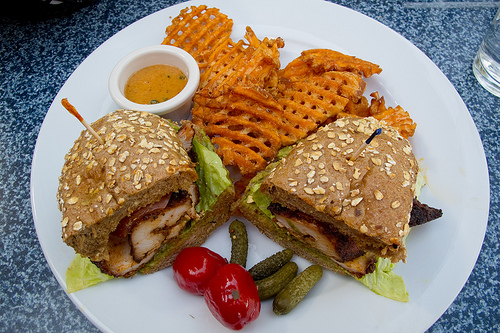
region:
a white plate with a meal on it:
[31, 0, 491, 332]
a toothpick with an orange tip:
[60, 97, 103, 147]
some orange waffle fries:
[199, 5, 373, 120]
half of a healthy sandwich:
[58, 109, 230, 275]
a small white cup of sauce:
[108, 43, 199, 118]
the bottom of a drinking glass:
[472, 2, 499, 101]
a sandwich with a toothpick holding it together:
[241, 115, 417, 278]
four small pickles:
[228, 218, 323, 316]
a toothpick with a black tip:
[349, 127, 382, 162]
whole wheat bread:
[62, 109, 192, 218]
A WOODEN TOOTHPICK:
[45, 95, 120, 145]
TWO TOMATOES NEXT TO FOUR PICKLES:
[150, 211, 331, 326]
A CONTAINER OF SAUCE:
[105, 40, 207, 115]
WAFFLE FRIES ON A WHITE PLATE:
[157, 1, 427, 168]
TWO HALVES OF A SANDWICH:
[45, 91, 430, 287]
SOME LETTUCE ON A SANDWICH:
[176, 120, 238, 220]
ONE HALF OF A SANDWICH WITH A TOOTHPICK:
[230, 110, 435, 295]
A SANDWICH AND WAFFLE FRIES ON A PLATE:
[20, 5, 490, 325]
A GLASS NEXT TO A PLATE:
[460, 10, 495, 100]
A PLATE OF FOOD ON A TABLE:
[10, 10, 490, 325]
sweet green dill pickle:
[237, 242, 326, 314]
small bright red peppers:
[161, 239, 264, 330]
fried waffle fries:
[205, 20, 387, 170]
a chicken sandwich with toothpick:
[55, 107, 242, 292]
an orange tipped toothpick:
[50, 87, 115, 160]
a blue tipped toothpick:
[349, 108, 393, 175]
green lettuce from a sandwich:
[173, 116, 313, 241]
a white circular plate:
[27, 2, 481, 330]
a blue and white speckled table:
[4, 12, 90, 331]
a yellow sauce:
[93, 32, 219, 128]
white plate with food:
[36, 38, 461, 310]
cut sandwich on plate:
[49, 89, 468, 299]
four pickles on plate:
[227, 207, 344, 301]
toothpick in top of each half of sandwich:
[43, 84, 425, 240]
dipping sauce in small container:
[102, 27, 248, 117]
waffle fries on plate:
[144, 27, 385, 153]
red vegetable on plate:
[139, 226, 261, 332]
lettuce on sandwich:
[47, 106, 283, 235]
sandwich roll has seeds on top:
[61, 94, 255, 274]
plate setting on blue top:
[33, 31, 495, 318]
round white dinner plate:
[33, 7, 498, 330]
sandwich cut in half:
[46, 93, 446, 272]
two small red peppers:
[161, 229, 264, 324]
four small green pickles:
[224, 208, 321, 318]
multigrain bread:
[56, 106, 430, 225]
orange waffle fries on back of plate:
[170, 10, 375, 160]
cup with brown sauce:
[110, 45, 216, 131]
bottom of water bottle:
[473, 29, 498, 77]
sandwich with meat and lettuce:
[51, 100, 436, 280]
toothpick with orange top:
[52, 91, 112, 156]